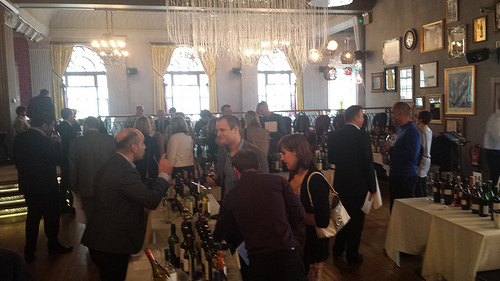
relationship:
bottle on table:
[426, 161, 493, 216] [389, 191, 487, 275]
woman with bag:
[258, 131, 336, 273] [304, 170, 351, 239]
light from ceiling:
[163, 37, 253, 76] [167, 20, 254, 54]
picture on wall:
[417, 31, 434, 45] [351, 26, 470, 121]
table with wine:
[389, 191, 487, 275] [425, 172, 482, 211]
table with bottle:
[389, 191, 487, 275] [426, 161, 493, 216]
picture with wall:
[417, 31, 434, 45] [351, 26, 470, 121]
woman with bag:
[258, 131, 336, 273] [284, 165, 347, 248]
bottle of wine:
[426, 161, 493, 216] [425, 172, 482, 211]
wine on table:
[425, 172, 482, 211] [389, 191, 487, 275]